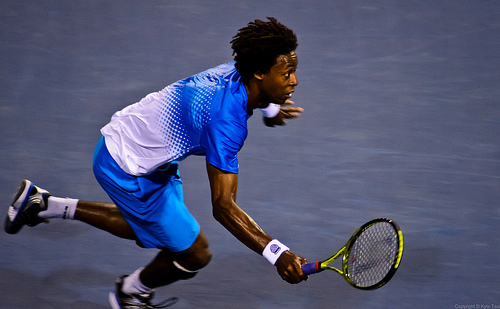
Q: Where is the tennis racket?
A: In his right hand.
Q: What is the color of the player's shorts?
A: Blue.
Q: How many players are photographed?
A: One.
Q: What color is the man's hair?
A: Black.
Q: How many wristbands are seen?
A: Two.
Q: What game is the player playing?
A: Tennis.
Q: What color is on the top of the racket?
A: Yellow.